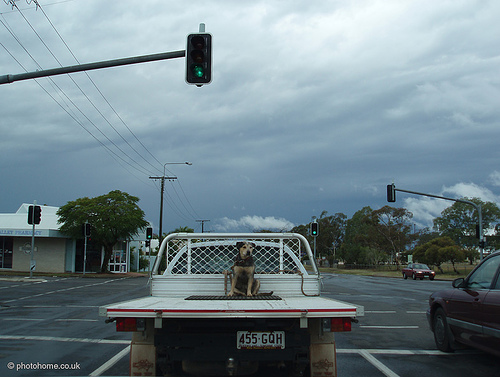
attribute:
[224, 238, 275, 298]
dog — black, brown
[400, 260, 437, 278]
car — red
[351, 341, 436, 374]
stripe — white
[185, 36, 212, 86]
traffic light — green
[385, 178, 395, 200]
traffic light — green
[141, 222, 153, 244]
traffic light — green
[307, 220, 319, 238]
traffic light — green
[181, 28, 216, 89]
traffic light — green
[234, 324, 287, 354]
license plate — white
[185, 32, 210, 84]
traffic light — green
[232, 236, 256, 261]
dog head — black, brown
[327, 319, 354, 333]
tail light — red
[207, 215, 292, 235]
cloud — white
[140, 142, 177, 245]
pole — telephone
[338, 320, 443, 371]
stripes — white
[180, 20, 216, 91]
traffic — green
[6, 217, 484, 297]
view — partial